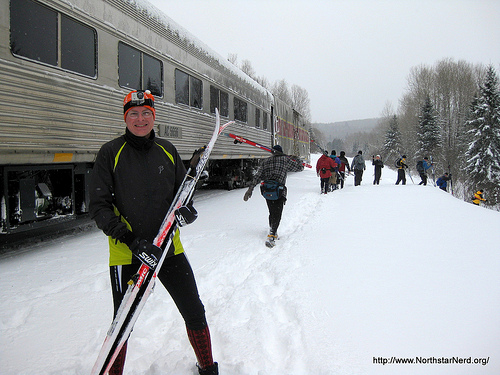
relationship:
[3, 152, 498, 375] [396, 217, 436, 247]
snow on ground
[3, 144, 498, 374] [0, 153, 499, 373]
snow on ground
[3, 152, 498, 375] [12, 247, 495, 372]
snow on ground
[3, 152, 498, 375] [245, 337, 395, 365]
snow on ground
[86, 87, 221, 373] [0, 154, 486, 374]
skiier on trail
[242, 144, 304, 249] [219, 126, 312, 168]
man carrying skis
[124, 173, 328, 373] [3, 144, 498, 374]
path in snow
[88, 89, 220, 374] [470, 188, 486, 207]
skiier in yellow jacket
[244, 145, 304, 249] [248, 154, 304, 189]
man wearing shirt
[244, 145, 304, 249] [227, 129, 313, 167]
man carrying skiis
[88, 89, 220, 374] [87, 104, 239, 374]
skiier holding skis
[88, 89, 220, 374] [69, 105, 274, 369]
skiier dressed in attire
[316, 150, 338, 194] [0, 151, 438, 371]
person in snow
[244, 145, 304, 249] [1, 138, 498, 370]
man walking down hill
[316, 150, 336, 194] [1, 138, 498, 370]
person walking down hill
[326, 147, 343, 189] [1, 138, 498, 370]
person walking down hill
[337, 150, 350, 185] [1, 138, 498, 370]
person walking down hill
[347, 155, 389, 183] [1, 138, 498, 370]
person walking down hill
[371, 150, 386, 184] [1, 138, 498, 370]
person walking down hill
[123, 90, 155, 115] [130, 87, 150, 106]
orange hat with camera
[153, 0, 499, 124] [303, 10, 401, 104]
clouds in sky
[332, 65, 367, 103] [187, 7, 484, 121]
clouds in sky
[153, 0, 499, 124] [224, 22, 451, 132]
clouds in sky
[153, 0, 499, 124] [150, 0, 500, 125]
clouds in clouds sky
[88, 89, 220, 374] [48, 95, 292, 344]
skiier holding skis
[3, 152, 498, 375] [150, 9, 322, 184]
snow covered train